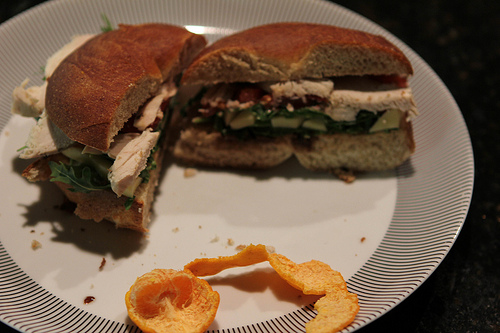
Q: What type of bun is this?
A: Whole wheat.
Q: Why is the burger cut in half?
A: Easier to hold.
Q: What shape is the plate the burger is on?
A: Round.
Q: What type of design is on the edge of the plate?
A: Stripes.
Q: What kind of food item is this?
A: Sandwich.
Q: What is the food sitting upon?
A: Plate.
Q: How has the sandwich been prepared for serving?
A: Cut in half.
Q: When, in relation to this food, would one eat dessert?
A: Afterwards.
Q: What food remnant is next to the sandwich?
A: Peel.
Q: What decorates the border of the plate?
A: Thin stripes.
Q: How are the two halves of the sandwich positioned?
A: Perpendicular to each other.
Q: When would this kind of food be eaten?
A: Lunch or dinner.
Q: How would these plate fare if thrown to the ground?
A: It would break.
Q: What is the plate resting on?
A: Table.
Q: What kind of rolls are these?
A: Kaiser rolls.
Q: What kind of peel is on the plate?
A: Orange.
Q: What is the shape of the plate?
A: Circle.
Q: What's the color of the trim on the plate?
A: Black and white.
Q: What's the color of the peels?
A: Orange.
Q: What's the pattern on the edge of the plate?
A: Striped.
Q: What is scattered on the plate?
A: Crumbs.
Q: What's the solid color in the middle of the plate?
A: White.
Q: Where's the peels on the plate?
A: On the edge.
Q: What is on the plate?
A: A sandwich.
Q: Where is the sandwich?
A: On the plate.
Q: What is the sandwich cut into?
A: Halves.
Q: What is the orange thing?
A: An orange.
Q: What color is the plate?
A: White.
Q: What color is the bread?
A: Brown.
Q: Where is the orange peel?
A: In front of the sandwich.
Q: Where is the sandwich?
A: Behind the orange peel.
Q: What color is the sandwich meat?
A: White.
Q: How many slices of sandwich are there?
A: Two.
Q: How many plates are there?
A: One.